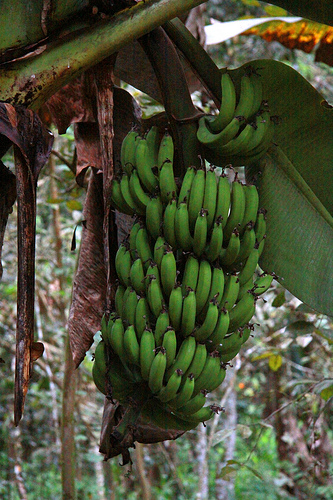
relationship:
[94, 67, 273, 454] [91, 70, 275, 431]
bunch of bunch